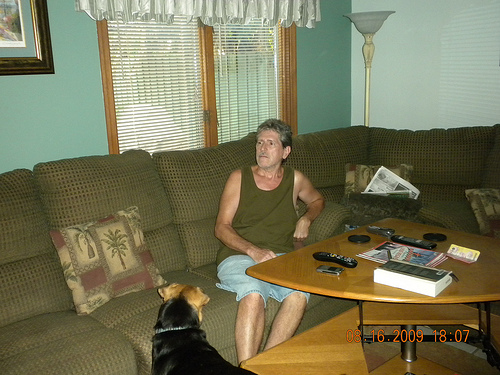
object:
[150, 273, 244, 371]
dog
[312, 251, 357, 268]
controller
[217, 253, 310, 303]
shorts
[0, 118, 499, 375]
couch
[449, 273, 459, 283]
bookmark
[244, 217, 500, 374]
coffee table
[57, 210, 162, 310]
palm trees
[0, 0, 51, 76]
picture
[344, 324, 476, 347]
numbers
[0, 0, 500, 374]
picture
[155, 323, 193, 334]
collar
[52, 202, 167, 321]
pillow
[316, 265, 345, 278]
cell phone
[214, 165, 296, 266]
tank top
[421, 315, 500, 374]
floor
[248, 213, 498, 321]
table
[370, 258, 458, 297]
book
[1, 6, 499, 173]
wall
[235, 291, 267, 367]
leg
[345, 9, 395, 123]
floor lamp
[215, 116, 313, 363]
man